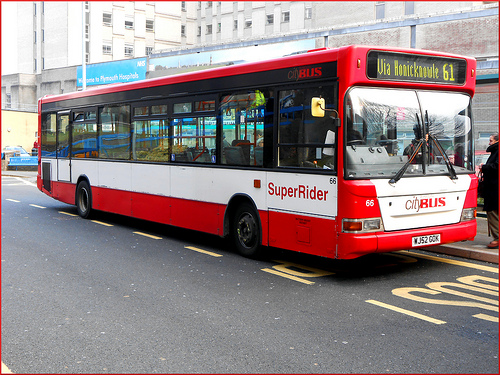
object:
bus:
[35, 42, 480, 262]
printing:
[267, 181, 275, 197]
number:
[442, 63, 449, 82]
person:
[477, 130, 500, 250]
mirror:
[310, 96, 327, 118]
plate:
[411, 233, 441, 247]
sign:
[75, 56, 149, 89]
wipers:
[389, 112, 431, 184]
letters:
[387, 284, 498, 327]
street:
[0, 169, 500, 372]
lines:
[259, 266, 318, 287]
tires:
[228, 200, 260, 258]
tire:
[74, 179, 93, 219]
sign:
[365, 48, 467, 86]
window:
[273, 80, 340, 174]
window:
[98, 103, 132, 163]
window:
[69, 106, 100, 160]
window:
[131, 104, 170, 163]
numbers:
[369, 199, 374, 207]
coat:
[480, 140, 500, 211]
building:
[12, 0, 500, 74]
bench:
[7, 155, 39, 171]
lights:
[363, 216, 384, 234]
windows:
[102, 10, 114, 28]